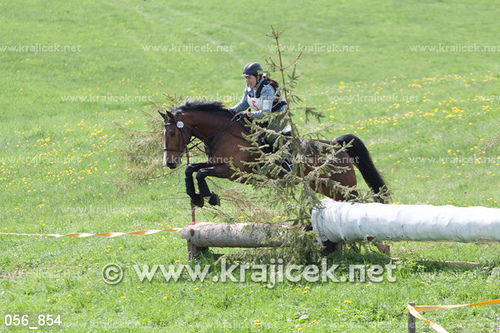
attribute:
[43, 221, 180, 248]
rope — is orange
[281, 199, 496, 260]
pipe — long, metal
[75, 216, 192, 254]
rope — orange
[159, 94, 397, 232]
horse — brown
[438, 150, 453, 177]
ground — green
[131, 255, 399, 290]
address — is www.krajicek.net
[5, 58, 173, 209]
flowers —  yellow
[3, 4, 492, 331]
grass — yellow and green, short, yellow, green, green and yellow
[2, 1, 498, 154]
grass — yellow and green, short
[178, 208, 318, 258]
poll — wooden, brown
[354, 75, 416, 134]
yello grass — short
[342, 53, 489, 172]
grass — short, green and yellow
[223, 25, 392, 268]
fur tree — small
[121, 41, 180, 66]
grass — short, yellow and green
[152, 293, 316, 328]
grass — short, yellow and green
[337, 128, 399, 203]
tail — long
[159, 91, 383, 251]
horse — hairy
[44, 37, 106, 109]
grass — yellow and green, short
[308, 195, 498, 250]
wrapping — white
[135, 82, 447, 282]
horse — large, brown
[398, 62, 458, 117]
grass — short, yellow and green